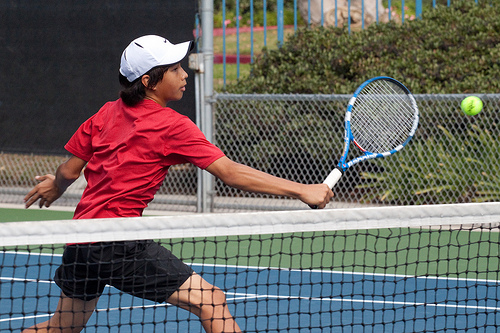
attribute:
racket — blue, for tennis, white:
[309, 75, 419, 209]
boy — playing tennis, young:
[23, 35, 335, 333]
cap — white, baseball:
[118, 34, 194, 87]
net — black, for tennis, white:
[0, 202, 498, 333]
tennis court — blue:
[1, 208, 500, 331]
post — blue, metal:
[222, 1, 226, 91]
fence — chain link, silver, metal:
[207, 92, 500, 211]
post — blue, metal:
[249, 1, 255, 71]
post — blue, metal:
[277, 0, 284, 46]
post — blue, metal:
[306, 0, 311, 26]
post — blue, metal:
[334, 1, 340, 31]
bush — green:
[209, 3, 500, 198]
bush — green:
[354, 122, 499, 206]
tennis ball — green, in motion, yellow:
[462, 97, 483, 118]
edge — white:
[0, 202, 499, 248]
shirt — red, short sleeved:
[63, 98, 225, 220]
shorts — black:
[54, 238, 194, 303]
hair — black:
[118, 65, 169, 107]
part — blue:
[0, 252, 499, 332]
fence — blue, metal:
[213, 0, 494, 92]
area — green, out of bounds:
[1, 207, 499, 281]